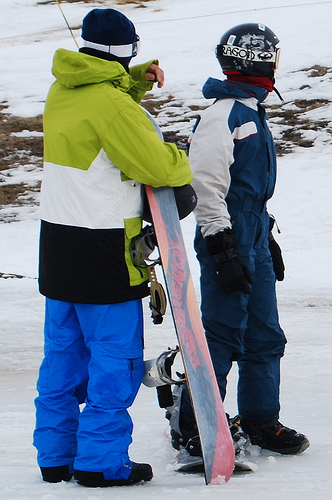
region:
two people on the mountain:
[23, 3, 306, 490]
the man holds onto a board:
[106, 101, 242, 493]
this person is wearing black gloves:
[204, 215, 294, 288]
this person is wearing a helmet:
[212, 22, 283, 88]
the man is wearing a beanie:
[76, 3, 134, 70]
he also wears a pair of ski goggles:
[83, 30, 145, 59]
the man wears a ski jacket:
[37, 47, 189, 314]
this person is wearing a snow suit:
[167, 71, 296, 467]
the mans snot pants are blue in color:
[35, 294, 146, 472]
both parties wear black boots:
[31, 415, 331, 489]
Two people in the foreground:
[23, 1, 317, 489]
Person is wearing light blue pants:
[24, 295, 148, 475]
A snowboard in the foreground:
[113, 103, 251, 490]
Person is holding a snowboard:
[12, 3, 253, 489]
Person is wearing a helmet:
[208, 11, 294, 100]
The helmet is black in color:
[211, 18, 286, 93]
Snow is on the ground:
[0, 0, 327, 498]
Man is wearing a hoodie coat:
[20, 43, 188, 307]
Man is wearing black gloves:
[199, 212, 290, 295]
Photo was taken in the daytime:
[0, 3, 331, 499]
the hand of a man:
[128, 47, 189, 94]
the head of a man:
[68, 14, 153, 74]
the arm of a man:
[169, 94, 265, 305]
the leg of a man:
[236, 258, 314, 465]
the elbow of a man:
[137, 118, 210, 199]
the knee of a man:
[235, 309, 308, 384]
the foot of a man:
[242, 388, 327, 480]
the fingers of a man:
[127, 41, 189, 111]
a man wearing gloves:
[202, 255, 268, 315]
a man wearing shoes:
[234, 379, 316, 473]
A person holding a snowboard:
[31, 5, 239, 488]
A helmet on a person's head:
[212, 19, 285, 89]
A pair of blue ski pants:
[29, 296, 145, 481]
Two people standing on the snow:
[30, 6, 312, 497]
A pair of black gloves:
[201, 214, 287, 297]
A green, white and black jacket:
[36, 46, 193, 306]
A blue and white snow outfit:
[182, 18, 289, 422]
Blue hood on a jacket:
[196, 75, 253, 104]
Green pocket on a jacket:
[121, 214, 153, 287]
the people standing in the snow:
[30, 2, 308, 488]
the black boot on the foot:
[247, 418, 310, 458]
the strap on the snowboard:
[139, 345, 194, 412]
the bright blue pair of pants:
[35, 293, 143, 481]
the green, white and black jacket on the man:
[39, 50, 189, 298]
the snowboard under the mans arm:
[153, 184, 238, 483]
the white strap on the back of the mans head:
[83, 38, 140, 58]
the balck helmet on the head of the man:
[214, 24, 278, 79]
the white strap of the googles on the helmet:
[221, 41, 274, 66]